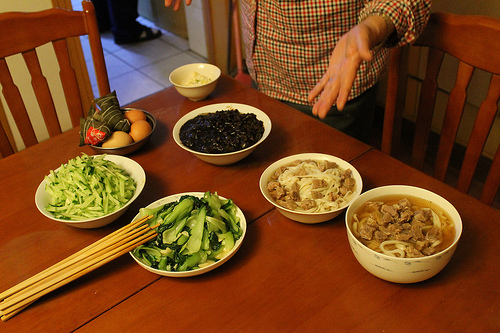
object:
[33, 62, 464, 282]
food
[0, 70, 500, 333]
table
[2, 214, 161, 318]
chopstick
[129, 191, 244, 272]
bokchoy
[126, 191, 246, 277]
plate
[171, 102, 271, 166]
bowl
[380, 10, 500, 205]
chairs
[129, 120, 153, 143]
eggs